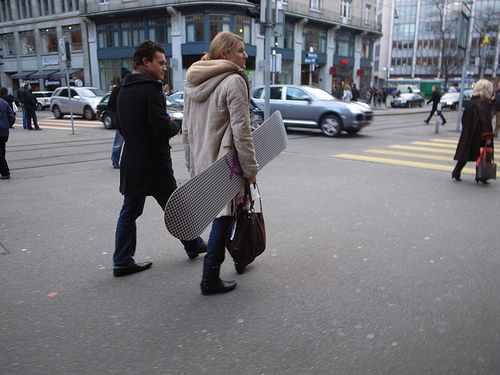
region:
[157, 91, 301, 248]
Black and white board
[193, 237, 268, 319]
Woman is wearing black boots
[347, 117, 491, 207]
Yellow lines on the asphalt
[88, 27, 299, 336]
The people are walking on asphalt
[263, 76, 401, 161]
The car is grey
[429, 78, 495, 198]
Women carrying a brown bag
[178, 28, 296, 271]
Women carrying a long board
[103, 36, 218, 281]
Man wearing a black coat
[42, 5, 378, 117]
White and green building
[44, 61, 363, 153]
Cars driving on the street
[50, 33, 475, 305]
picture taken outdoors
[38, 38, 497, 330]
picture taken during the day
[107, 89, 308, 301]
a man an a woman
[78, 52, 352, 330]
the people are walking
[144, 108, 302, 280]
the woman is holding a snow board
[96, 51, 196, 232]
the man is wearing a black coat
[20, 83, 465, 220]
many people walking on the streets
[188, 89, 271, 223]
the woman is wearing a large coat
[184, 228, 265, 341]
the woman is wearing boots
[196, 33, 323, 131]
the woman is looking to the right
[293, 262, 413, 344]
Grey concrete beneath the people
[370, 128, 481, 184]
A crosswalk on the street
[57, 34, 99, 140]
A tall metal pole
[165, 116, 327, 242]
A white and black snowboard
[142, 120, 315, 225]
The snowboard is checkered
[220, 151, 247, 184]
A pink "X" on the snowboard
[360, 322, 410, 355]
White flecks of paint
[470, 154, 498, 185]
A brown purse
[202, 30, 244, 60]
Blonde hair on the woman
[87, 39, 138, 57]
A blue balcony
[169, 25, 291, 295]
woman walking on street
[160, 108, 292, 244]
snowboard in woman's hand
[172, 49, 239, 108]
hood on back of coat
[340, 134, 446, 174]
yellow lines in road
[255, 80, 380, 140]
car in street intersection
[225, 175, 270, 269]
purse in woman's hand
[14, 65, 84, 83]
awnings on side of building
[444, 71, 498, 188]
woman walking with bags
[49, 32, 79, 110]
sign on metal pole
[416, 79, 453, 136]
man walking across street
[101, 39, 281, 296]
a couple walking down the street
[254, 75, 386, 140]
a silver car driving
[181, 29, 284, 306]
a woman carrying a snowboard and handbag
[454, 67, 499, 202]
a woman wearing a long coat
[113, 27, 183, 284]
a man wearing dark clothing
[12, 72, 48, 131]
two people waiting to cross the street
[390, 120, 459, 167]
yellow lines marking the crosswalk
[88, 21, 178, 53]
glass windows on the side of a building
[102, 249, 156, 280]
black designer shoe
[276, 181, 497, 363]
gray concrete on the sidewalk